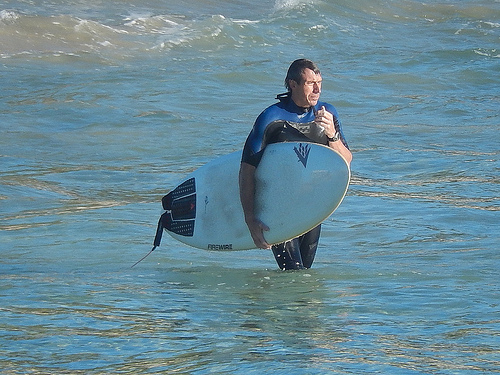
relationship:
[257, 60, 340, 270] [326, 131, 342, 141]
man wearing a watch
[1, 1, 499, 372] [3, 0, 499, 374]
waters in sea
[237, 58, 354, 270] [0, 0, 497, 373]
man in water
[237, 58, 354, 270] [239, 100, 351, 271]
man wearing wetsuit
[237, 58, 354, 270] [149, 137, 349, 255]
man holding surfboard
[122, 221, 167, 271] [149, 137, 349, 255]
cord on surfboard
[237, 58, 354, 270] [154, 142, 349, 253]
man holding white board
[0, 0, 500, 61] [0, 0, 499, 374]
wave of sea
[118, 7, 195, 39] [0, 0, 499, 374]
wave of sea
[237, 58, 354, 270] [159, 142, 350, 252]
man carrying white board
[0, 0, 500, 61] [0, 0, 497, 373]
wave in water